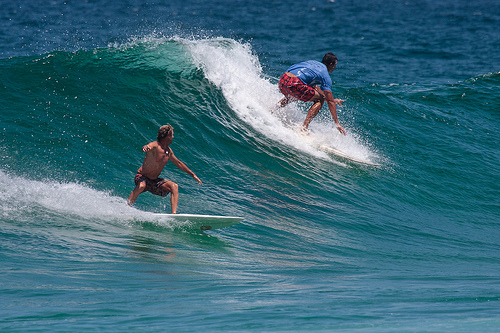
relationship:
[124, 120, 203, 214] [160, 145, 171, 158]
man wearing necklace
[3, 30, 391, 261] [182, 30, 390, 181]
wave has whitecap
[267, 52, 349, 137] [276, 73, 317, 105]
surfer wearing bathing suit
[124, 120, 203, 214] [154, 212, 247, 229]
man riding surfboard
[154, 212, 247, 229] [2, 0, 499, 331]
surfboard in water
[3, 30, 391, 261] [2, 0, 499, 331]
wave in water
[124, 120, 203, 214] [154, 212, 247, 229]
man surfing on surfboard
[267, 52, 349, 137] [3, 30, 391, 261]
surfer trying to catch wave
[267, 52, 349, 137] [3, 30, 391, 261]
surfer catching wave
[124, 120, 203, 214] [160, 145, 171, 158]
man has necklace